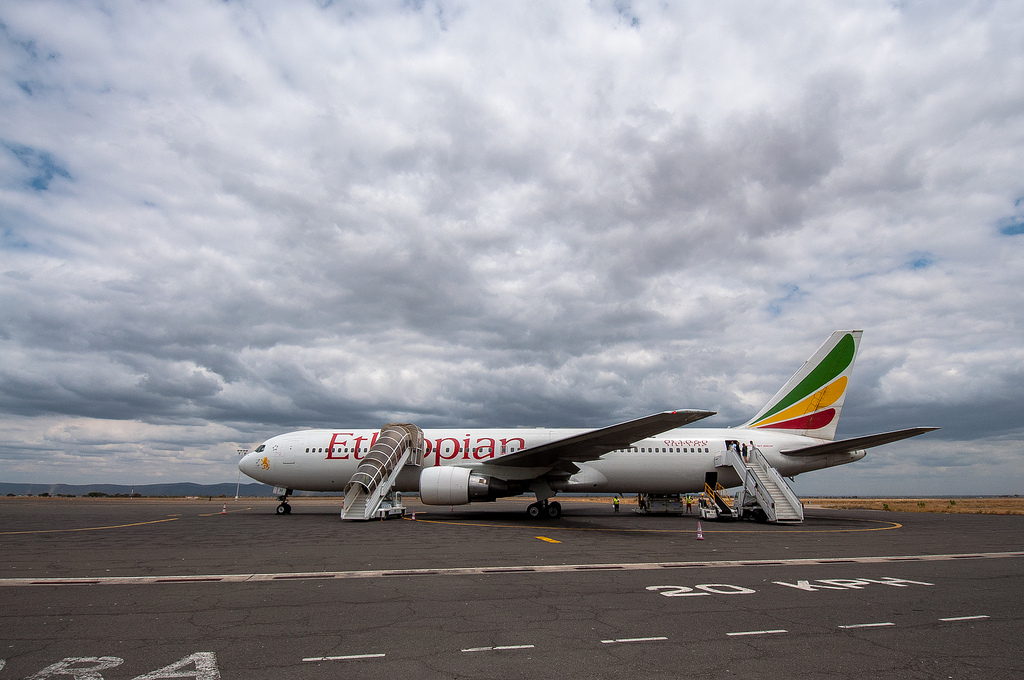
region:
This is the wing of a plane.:
[480, 400, 722, 476]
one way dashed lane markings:
[288, 607, 985, 669]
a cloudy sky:
[53, 1, 708, 393]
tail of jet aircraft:
[762, 313, 895, 463]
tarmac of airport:
[222, 524, 849, 676]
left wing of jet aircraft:
[462, 402, 738, 501]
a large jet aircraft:
[227, 309, 896, 529]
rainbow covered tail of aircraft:
[745, 312, 897, 437]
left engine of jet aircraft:
[411, 449, 501, 516]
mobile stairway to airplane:
[335, 426, 421, 525]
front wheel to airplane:
[269, 490, 311, 517]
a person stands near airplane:
[604, 487, 637, 522]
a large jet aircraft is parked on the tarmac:
[246, 313, 935, 525]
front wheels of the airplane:
[269, 494, 305, 517]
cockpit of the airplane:
[238, 432, 286, 496]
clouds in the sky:
[18, 22, 1014, 326]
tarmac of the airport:
[10, 518, 1007, 651]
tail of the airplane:
[783, 313, 942, 506]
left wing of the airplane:
[484, 395, 719, 475]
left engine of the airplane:
[404, 458, 509, 513]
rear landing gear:
[522, 493, 573, 525]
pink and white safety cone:
[690, 513, 711, 546]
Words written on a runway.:
[637, 577, 942, 596]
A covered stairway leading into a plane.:
[342, 422, 412, 524]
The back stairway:
[721, 434, 808, 526]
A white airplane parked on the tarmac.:
[225, 342, 924, 505]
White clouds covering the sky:
[24, 55, 990, 327]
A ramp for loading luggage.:
[697, 469, 745, 523]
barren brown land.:
[825, 482, 1022, 512]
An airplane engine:
[412, 460, 521, 505]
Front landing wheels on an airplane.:
[269, 485, 302, 515]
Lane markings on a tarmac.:
[308, 604, 1017, 669]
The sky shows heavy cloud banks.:
[256, 99, 1021, 365]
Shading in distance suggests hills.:
[41, 454, 267, 557]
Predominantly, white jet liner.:
[232, 424, 969, 549]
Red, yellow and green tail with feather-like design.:
[754, 368, 892, 520]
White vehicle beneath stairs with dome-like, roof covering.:
[339, 433, 420, 604]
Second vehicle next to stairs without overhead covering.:
[700, 446, 802, 548]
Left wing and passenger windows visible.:
[482, 433, 831, 498]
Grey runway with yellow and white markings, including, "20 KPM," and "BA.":
[36, 454, 1019, 645]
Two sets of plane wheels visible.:
[270, 488, 624, 553]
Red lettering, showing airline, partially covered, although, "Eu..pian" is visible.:
[318, 429, 562, 480]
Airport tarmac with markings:
[16, 529, 1010, 666]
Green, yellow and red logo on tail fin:
[717, 301, 879, 437]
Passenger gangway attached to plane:
[714, 433, 823, 523]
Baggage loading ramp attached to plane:
[692, 458, 746, 523]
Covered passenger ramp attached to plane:
[341, 426, 424, 525]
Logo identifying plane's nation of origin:
[310, 417, 546, 471]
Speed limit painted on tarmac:
[612, 566, 961, 602]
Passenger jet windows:
[294, 434, 721, 464]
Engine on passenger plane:
[422, 430, 503, 525]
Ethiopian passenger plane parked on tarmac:
[189, 290, 962, 569]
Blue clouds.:
[78, 96, 601, 365]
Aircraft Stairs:
[751, 452, 806, 528]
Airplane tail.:
[768, 363, 855, 443]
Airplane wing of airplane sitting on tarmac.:
[510, 397, 703, 467]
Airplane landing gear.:
[269, 482, 296, 522]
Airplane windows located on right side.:
[596, 435, 710, 455]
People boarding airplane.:
[715, 422, 773, 455]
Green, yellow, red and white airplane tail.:
[751, 315, 866, 439]